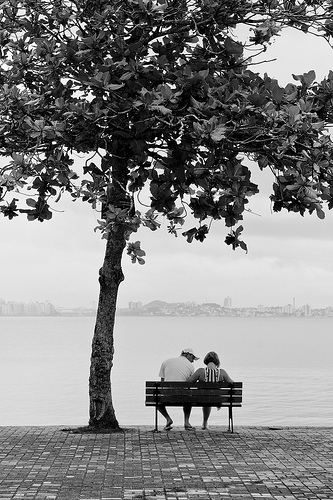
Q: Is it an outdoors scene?
A: Yes, it is outdoors.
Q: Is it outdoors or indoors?
A: It is outdoors.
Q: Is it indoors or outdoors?
A: It is outdoors.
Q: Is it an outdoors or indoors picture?
A: It is outdoors.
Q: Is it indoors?
A: No, it is outdoors.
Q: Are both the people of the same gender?
A: No, they are both male and female.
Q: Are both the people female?
A: No, they are both male and female.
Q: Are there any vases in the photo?
A: No, there are no vases.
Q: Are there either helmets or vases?
A: No, there are no vases or helmets.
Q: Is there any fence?
A: No, there are no fences.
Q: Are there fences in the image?
A: No, there are no fences.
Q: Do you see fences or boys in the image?
A: No, there are no fences or boys.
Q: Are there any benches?
A: Yes, there is a bench.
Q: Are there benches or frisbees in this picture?
A: Yes, there is a bench.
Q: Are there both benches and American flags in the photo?
A: No, there is a bench but no American flags.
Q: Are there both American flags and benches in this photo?
A: No, there is a bench but no American flags.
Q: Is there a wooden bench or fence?
A: Yes, there is a wood bench.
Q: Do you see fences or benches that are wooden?
A: Yes, the bench is wooden.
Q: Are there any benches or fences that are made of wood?
A: Yes, the bench is made of wood.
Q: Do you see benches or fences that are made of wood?
A: Yes, the bench is made of wood.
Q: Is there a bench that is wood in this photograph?
A: Yes, there is a wood bench.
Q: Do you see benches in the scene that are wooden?
A: Yes, there is a bench that is wooden.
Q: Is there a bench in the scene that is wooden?
A: Yes, there is a bench that is wooden.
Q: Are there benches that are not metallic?
A: Yes, there is a wooden bench.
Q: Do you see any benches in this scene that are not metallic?
A: Yes, there is a wooden bench.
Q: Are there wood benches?
A: Yes, there is a bench that is made of wood.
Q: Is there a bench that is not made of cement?
A: Yes, there is a bench that is made of wood.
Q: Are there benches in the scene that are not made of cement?
A: Yes, there is a bench that is made of wood.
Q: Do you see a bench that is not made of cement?
A: Yes, there is a bench that is made of wood.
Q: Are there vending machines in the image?
A: No, there are no vending machines.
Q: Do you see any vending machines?
A: No, there are no vending machines.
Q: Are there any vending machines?
A: No, there are no vending machines.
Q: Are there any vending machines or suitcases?
A: No, there are no vending machines or suitcases.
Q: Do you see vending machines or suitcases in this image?
A: No, there are no vending machines or suitcases.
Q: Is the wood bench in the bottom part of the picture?
A: Yes, the bench is in the bottom of the image.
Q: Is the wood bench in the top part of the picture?
A: No, the bench is in the bottom of the image.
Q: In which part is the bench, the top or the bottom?
A: The bench is in the bottom of the image.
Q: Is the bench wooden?
A: Yes, the bench is wooden.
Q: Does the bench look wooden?
A: Yes, the bench is wooden.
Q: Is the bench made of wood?
A: Yes, the bench is made of wood.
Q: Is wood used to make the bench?
A: Yes, the bench is made of wood.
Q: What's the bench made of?
A: The bench is made of wood.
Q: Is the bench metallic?
A: No, the bench is wooden.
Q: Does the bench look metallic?
A: No, the bench is wooden.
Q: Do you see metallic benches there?
A: No, there is a bench but it is wooden.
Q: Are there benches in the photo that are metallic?
A: No, there is a bench but it is wooden.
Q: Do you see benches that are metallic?
A: No, there is a bench but it is wooden.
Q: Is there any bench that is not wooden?
A: No, there is a bench but it is wooden.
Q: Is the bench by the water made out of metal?
A: No, the bench is made of wood.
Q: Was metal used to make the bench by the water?
A: No, the bench is made of wood.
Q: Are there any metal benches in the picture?
A: No, there is a bench but it is made of wood.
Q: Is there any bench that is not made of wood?
A: No, there is a bench but it is made of wood.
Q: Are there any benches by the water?
A: Yes, there is a bench by the water.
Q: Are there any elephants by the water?
A: No, there is a bench by the water.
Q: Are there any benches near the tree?
A: Yes, there is a bench near the tree.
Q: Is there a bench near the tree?
A: Yes, there is a bench near the tree.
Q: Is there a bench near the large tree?
A: Yes, there is a bench near the tree.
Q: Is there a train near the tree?
A: No, there is a bench near the tree.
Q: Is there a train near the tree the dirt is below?
A: No, there is a bench near the tree.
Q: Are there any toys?
A: No, there are no toys.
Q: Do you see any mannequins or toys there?
A: No, there are no toys or mannequins.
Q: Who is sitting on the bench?
A: The couple is sitting on the bench.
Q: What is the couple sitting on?
A: The couple is sitting on the bench.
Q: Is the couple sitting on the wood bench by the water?
A: Yes, the couple is sitting on the bench.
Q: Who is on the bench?
A: The couple is on the bench.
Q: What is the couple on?
A: The couple is on the bench.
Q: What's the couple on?
A: The couple is on the bench.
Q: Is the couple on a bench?
A: Yes, the couple is on a bench.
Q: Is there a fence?
A: No, there are no fences.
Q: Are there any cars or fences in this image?
A: No, there are no fences or cars.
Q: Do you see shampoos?
A: No, there are no shampoos.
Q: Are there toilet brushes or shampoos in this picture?
A: No, there are no shampoos or toilet brushes.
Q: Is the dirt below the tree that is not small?
A: Yes, the dirt is below the tree.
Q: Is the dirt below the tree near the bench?
A: Yes, the dirt is below the tree.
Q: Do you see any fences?
A: No, there are no fences.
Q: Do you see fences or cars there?
A: No, there are no fences or cars.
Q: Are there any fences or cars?
A: No, there are no fences or cars.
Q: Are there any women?
A: Yes, there is a woman.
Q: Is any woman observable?
A: Yes, there is a woman.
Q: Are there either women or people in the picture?
A: Yes, there is a woman.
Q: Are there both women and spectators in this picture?
A: No, there is a woman but no spectators.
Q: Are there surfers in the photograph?
A: No, there are no surfers.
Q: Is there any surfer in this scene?
A: No, there are no surfers.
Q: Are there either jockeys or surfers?
A: No, there are no surfers or jockeys.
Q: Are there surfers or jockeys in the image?
A: No, there are no surfers or jockeys.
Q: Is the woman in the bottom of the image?
A: Yes, the woman is in the bottom of the image.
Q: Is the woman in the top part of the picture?
A: No, the woman is in the bottom of the image.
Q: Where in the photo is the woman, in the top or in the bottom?
A: The woman is in the bottom of the image.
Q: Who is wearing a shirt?
A: The woman is wearing a shirt.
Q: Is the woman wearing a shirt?
A: Yes, the woman is wearing a shirt.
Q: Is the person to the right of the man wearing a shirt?
A: Yes, the woman is wearing a shirt.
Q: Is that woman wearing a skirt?
A: No, the woman is wearing a shirt.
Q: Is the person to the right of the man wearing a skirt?
A: No, the woman is wearing a shirt.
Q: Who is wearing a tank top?
A: The woman is wearing a tank top.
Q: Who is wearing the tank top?
A: The woman is wearing a tank top.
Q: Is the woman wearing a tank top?
A: Yes, the woman is wearing a tank top.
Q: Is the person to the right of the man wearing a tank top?
A: Yes, the woman is wearing a tank top.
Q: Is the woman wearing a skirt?
A: No, the woman is wearing a tank top.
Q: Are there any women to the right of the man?
A: Yes, there is a woman to the right of the man.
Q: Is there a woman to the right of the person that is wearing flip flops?
A: Yes, there is a woman to the right of the man.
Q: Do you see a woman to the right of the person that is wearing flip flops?
A: Yes, there is a woman to the right of the man.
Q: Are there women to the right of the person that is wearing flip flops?
A: Yes, there is a woman to the right of the man.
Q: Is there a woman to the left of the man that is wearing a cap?
A: No, the woman is to the right of the man.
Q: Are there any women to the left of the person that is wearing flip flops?
A: No, the woman is to the right of the man.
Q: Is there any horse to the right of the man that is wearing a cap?
A: No, there is a woman to the right of the man.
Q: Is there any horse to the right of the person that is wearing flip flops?
A: No, there is a woman to the right of the man.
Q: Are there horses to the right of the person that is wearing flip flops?
A: No, there is a woman to the right of the man.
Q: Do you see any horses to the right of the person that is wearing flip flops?
A: No, there is a woman to the right of the man.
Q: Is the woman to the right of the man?
A: Yes, the woman is to the right of the man.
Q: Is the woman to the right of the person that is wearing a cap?
A: Yes, the woman is to the right of the man.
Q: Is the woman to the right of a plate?
A: No, the woman is to the right of the man.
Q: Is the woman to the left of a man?
A: No, the woman is to the right of a man.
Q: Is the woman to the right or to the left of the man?
A: The woman is to the right of the man.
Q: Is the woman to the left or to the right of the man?
A: The woman is to the right of the man.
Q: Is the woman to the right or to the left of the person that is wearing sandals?
A: The woman is to the right of the man.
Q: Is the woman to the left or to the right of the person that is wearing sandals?
A: The woman is to the right of the man.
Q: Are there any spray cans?
A: No, there are no spray cans.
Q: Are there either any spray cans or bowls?
A: No, there are no spray cans or bowls.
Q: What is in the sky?
A: The clouds are in the sky.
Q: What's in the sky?
A: The clouds are in the sky.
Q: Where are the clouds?
A: The clouds are in the sky.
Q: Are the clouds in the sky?
A: Yes, the clouds are in the sky.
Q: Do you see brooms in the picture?
A: No, there are no brooms.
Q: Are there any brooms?
A: No, there are no brooms.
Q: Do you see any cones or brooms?
A: No, there are no brooms or cones.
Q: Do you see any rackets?
A: No, there are no rackets.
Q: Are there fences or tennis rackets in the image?
A: No, there are no tennis rackets or fences.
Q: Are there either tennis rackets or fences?
A: No, there are no tennis rackets or fences.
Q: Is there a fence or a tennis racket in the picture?
A: No, there are no rackets or fences.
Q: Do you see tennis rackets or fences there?
A: No, there are no tennis rackets or fences.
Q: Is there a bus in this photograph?
A: No, there are no buses.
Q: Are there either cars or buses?
A: No, there are no buses or cars.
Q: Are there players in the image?
A: No, there are no players.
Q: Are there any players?
A: No, there are no players.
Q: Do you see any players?
A: No, there are no players.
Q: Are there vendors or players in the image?
A: No, there are no players or vendors.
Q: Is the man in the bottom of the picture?
A: Yes, the man is in the bottom of the image.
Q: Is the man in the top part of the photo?
A: No, the man is in the bottom of the image.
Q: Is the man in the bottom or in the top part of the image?
A: The man is in the bottom of the image.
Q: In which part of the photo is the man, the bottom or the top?
A: The man is in the bottom of the image.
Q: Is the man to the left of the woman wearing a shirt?
A: Yes, the man is wearing a shirt.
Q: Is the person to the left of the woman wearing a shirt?
A: Yes, the man is wearing a shirt.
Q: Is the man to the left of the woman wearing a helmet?
A: No, the man is wearing a shirt.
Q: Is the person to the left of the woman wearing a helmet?
A: No, the man is wearing a shirt.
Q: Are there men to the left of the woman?
A: Yes, there is a man to the left of the woman.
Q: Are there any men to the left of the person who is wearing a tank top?
A: Yes, there is a man to the left of the woman.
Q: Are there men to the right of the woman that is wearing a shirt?
A: No, the man is to the left of the woman.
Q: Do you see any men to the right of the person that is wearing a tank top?
A: No, the man is to the left of the woman.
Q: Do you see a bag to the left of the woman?
A: No, there is a man to the left of the woman.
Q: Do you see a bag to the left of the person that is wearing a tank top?
A: No, there is a man to the left of the woman.